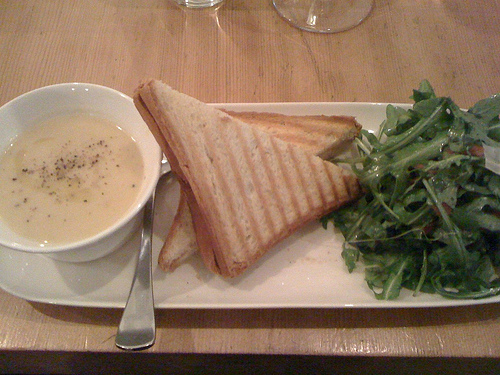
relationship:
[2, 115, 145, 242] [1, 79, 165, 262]
soup in bowl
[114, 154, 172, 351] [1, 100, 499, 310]
spoon on plate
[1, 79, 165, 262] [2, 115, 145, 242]
bowl of soup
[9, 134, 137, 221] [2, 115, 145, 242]
pepper on soup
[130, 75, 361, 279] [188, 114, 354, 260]
sandwich has lines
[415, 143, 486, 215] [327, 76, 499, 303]
tomatoes under leaves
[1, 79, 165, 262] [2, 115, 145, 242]
bowl of sauce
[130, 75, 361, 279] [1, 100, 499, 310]
sandwich on plate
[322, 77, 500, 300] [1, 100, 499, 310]
salad on plate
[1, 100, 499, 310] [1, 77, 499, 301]
plate has food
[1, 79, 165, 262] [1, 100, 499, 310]
bowl on side of plate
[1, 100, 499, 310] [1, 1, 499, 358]
plate on table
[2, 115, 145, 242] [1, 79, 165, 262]
sauce in bowl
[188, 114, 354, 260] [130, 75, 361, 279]
lines on toast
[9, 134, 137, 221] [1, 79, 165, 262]
pepper in bowl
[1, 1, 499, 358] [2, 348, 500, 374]
table has edge